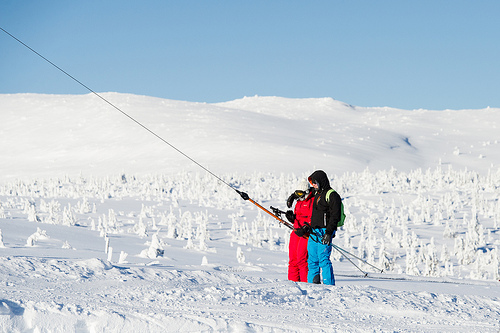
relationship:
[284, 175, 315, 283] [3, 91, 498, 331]
man standing in snow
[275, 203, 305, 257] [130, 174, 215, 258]
man standing on snow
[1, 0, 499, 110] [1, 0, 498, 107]
clouds in sky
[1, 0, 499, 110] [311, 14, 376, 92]
clouds in sky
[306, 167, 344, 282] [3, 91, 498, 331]
man standing on snow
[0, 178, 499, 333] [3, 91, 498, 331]
ground covered by snow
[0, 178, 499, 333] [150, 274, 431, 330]
ground covered by snow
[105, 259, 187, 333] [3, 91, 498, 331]
ground covered by snow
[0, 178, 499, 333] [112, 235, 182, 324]
ground covered by snow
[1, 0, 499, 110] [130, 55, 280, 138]
clouds in sky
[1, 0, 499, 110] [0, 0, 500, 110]
clouds in blue sky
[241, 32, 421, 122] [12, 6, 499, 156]
clouds in sky